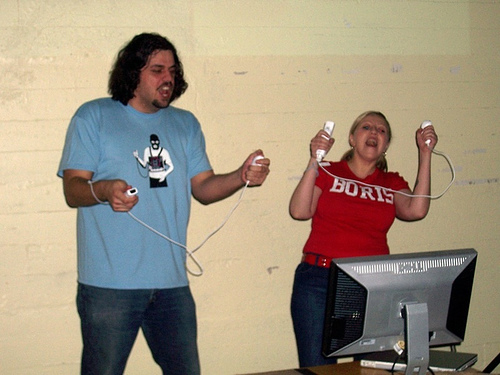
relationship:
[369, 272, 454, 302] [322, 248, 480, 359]
back of monitor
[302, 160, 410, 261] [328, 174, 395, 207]
shirt says boris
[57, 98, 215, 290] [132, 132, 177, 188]
shirt with picture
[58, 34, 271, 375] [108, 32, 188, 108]
man with hair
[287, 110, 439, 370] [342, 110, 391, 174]
woman with hair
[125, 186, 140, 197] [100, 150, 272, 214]
controller in hands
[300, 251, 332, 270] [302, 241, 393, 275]
belt on waist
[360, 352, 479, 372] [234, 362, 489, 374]
laptop on desk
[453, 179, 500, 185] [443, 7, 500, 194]
crack on wall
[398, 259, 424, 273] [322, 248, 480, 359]
words on monitor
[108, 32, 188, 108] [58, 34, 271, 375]
hair on man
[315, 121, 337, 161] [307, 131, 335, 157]
remote in hand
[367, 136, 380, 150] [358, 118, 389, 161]
grin on face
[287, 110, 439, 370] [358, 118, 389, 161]
woman has face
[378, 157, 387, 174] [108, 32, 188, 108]
streaks in hair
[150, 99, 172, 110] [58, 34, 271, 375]
beard on man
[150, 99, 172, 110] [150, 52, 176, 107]
beard on face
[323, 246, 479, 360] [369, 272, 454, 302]
television has back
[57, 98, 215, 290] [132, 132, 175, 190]
shirt has picture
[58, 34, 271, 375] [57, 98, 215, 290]
man in shirt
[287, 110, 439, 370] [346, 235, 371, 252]
woman in red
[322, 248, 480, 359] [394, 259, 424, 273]
monitor says words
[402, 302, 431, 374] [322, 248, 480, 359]
stand holds up monitor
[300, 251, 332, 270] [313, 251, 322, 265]
belt in loop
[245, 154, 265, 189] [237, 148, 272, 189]
nunchuck in mans hand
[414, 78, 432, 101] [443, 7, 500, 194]
paint on wall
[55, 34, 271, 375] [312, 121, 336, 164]
man playing controller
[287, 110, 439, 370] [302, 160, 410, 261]
woman in shirt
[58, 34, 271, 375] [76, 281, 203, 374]
man wearing jeans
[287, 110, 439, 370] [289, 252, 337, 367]
woman wearing jeans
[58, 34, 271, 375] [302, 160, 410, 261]
man wearing shirt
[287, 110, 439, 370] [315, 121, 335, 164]
woman holding controller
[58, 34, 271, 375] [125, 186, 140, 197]
man holding controller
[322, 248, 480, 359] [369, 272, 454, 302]
monitor has back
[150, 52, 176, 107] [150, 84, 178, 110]
face has hair